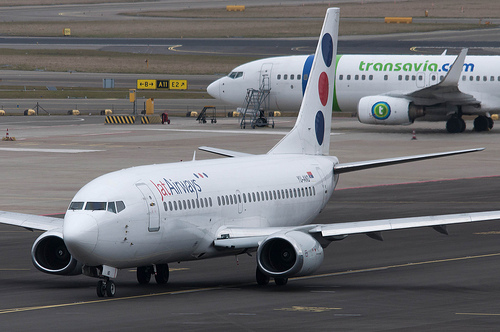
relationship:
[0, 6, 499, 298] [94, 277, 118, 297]
airplane on gear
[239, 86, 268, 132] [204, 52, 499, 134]
ladder to plane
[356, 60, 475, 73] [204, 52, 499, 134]
writing on plane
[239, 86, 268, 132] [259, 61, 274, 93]
ladder to door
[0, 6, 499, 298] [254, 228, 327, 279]
airplane has engine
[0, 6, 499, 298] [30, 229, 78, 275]
airplane has engine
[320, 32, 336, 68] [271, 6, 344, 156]
dot on tail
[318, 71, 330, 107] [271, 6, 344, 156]
dot on tail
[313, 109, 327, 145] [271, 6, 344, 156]
dot on tail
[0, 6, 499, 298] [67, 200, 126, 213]
airplane has windshield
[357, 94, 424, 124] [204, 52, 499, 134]
engine of plane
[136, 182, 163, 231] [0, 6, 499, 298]
door of airplane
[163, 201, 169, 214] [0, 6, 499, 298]
window on airplane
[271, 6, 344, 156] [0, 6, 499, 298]
tail of airplane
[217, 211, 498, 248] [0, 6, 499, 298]
wing of airplane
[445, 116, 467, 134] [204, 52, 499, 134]
wheel of plane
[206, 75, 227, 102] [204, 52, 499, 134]
nose of plane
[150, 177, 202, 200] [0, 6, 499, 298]
writing on airplane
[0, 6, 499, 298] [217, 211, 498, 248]
airplane has wing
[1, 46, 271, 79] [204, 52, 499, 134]
ground behind plane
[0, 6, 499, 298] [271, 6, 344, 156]
airplane has tail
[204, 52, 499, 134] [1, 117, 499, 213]
plane on tarmac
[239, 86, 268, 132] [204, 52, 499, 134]
ladder by plane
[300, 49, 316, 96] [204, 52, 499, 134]
stripe around plane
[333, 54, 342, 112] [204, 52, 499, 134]
stripe around plane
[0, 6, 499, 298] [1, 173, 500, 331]
airplane on runway